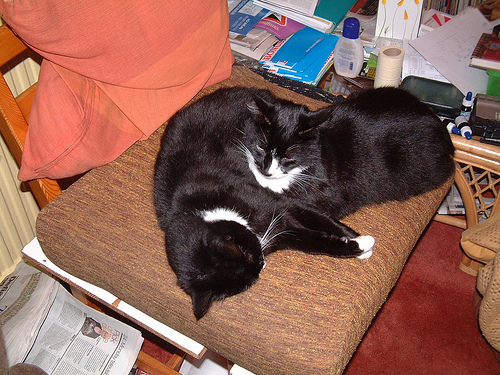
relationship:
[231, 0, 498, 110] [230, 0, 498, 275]
clutter on top of table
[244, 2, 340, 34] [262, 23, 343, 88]
papers next envelopes